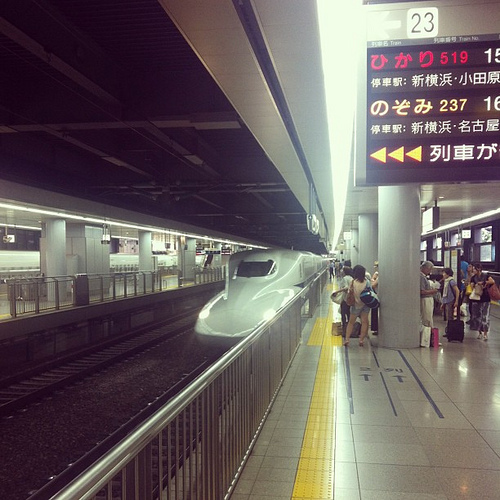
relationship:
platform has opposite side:
[167, 260, 498, 497] [0, 253, 239, 328]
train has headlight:
[189, 246, 326, 355] [258, 306, 277, 324]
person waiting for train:
[337, 264, 377, 350] [189, 246, 326, 355]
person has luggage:
[337, 264, 377, 350] [359, 288, 384, 313]